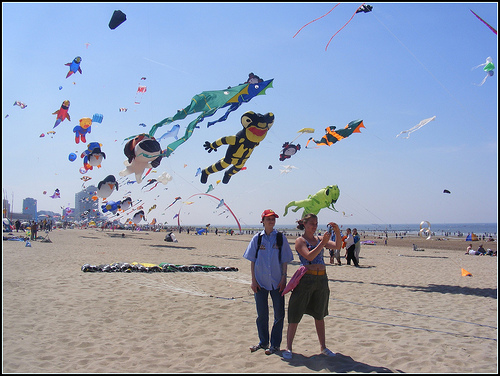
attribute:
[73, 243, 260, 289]
kite — large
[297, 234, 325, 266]
shirt — blue, sleeveless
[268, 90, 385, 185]
kite — white, black, brown, dog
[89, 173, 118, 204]
kite — black, white, penguin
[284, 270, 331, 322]
shorts — long, green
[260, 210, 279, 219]
baseball hat — orange